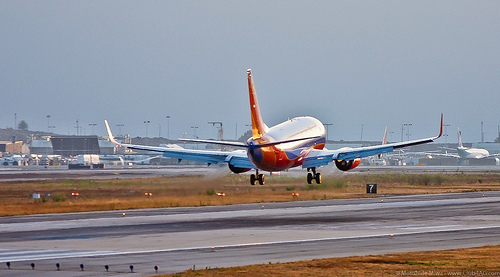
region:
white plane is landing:
[119, 106, 455, 192]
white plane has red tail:
[200, 67, 285, 170]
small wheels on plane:
[233, 157, 344, 204]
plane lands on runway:
[48, 94, 493, 231]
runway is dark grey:
[143, 204, 490, 275]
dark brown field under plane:
[25, 176, 229, 242]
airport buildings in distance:
[25, 115, 178, 176]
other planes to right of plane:
[368, 136, 495, 171]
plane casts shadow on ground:
[184, 200, 370, 252]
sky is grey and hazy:
[160, 41, 337, 93]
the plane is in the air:
[142, 85, 463, 189]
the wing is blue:
[308, 146, 415, 166]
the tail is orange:
[242, 79, 284, 150]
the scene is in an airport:
[44, 108, 474, 275]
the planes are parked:
[378, 122, 484, 174]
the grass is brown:
[395, 250, 473, 275]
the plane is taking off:
[156, 59, 458, 211]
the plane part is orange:
[246, 133, 293, 172]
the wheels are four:
[233, 166, 332, 200]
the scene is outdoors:
[10, 5, 487, 275]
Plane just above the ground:
[98, 66, 448, 188]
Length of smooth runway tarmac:
[2, 187, 496, 273]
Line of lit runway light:
[26, 184, 322, 203]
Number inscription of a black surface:
[363, 178, 377, 195]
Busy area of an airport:
[0, 121, 497, 175]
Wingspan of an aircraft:
[100, 111, 458, 166]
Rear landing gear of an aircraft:
[245, 169, 325, 187]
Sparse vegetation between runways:
[0, 167, 498, 220]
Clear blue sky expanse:
[0, 2, 497, 141]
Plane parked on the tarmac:
[451, 127, 498, 170]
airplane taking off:
[219, 145, 348, 213]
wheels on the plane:
[231, 170, 336, 194]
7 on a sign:
[353, 182, 384, 199]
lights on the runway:
[26, 250, 90, 274]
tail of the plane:
[249, 71, 277, 138]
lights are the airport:
[362, 117, 410, 130]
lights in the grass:
[49, 186, 302, 198]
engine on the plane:
[331, 148, 364, 177]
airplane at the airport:
[437, 120, 472, 166]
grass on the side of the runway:
[336, 236, 414, 272]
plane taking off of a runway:
[90, 70, 459, 200]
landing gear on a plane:
[242, 169, 267, 188]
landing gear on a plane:
[300, 168, 330, 190]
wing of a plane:
[100, 115, 255, 171]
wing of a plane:
[307, 114, 452, 166]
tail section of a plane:
[170, 60, 330, 165]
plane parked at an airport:
[403, 122, 496, 171]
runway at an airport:
[2, 186, 497, 275]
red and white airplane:
[90, 70, 472, 201]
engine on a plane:
[326, 145, 371, 172]